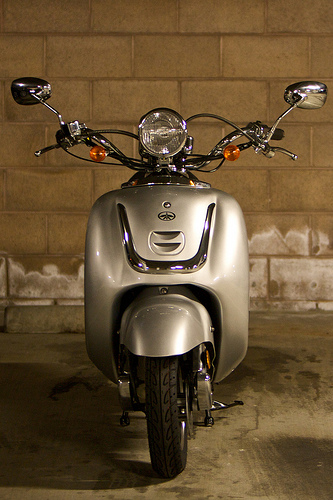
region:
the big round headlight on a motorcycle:
[140, 106, 184, 155]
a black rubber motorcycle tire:
[143, 363, 191, 477]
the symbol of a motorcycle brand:
[157, 211, 176, 219]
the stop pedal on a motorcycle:
[212, 395, 243, 411]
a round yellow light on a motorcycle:
[87, 146, 106, 159]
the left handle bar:
[213, 120, 284, 155]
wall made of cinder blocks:
[0, 1, 332, 311]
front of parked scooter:
[9, 76, 325, 477]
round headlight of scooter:
[137, 106, 186, 160]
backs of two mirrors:
[11, 75, 326, 126]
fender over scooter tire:
[120, 297, 216, 478]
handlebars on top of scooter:
[55, 115, 283, 172]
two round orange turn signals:
[90, 144, 239, 162]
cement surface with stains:
[1, 316, 331, 497]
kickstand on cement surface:
[119, 402, 214, 426]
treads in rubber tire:
[145, 356, 184, 480]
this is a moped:
[22, 11, 328, 494]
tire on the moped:
[99, 285, 223, 490]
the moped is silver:
[50, 170, 303, 439]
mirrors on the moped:
[6, 45, 331, 166]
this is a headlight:
[109, 93, 215, 167]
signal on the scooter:
[79, 140, 113, 163]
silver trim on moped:
[106, 187, 256, 288]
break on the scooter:
[229, 102, 301, 170]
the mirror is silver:
[258, 69, 331, 185]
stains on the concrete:
[248, 314, 329, 498]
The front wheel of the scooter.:
[127, 353, 217, 481]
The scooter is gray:
[20, 69, 309, 495]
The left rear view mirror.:
[8, 64, 82, 135]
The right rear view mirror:
[283, 70, 328, 114]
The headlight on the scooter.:
[132, 111, 201, 170]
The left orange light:
[84, 141, 123, 170]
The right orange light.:
[209, 143, 262, 172]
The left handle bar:
[30, 129, 91, 167]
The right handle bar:
[243, 116, 308, 164]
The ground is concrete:
[7, 312, 326, 498]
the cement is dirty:
[233, 360, 329, 493]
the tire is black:
[137, 363, 189, 493]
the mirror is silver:
[284, 82, 331, 121]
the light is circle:
[142, 110, 190, 155]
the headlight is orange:
[223, 144, 242, 172]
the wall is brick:
[16, 11, 303, 83]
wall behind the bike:
[9, 16, 282, 480]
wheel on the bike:
[112, 291, 234, 479]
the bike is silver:
[96, 194, 244, 385]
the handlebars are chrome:
[65, 121, 270, 167]